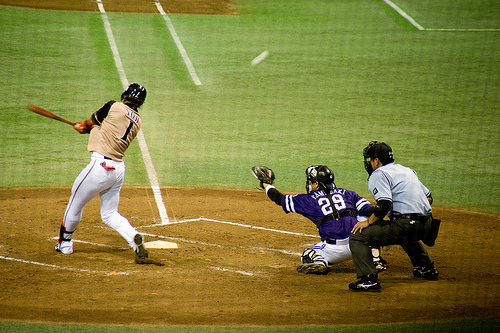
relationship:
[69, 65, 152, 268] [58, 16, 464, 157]
player on field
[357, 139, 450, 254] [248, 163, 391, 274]
umpire behind catcher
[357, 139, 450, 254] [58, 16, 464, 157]
umpire on field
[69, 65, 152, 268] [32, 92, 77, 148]
player swinging bat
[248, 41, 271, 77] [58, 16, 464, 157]
baseball on field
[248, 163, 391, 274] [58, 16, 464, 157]
catcher on field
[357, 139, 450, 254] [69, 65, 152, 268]
umpire behind player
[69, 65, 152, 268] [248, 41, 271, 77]
player near baseball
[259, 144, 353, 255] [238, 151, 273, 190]
catcher has mit